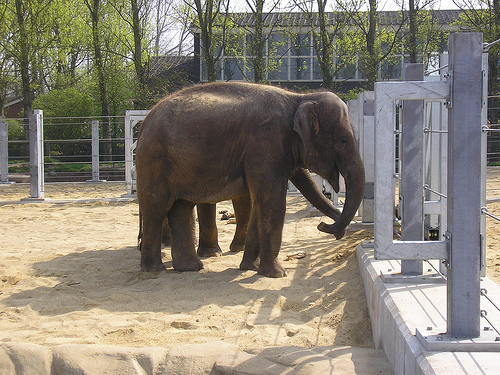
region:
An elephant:
[198, 91, 279, 248]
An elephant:
[208, 74, 400, 366]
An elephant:
[204, 108, 314, 289]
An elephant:
[173, 56, 336, 302]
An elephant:
[185, 48, 302, 214]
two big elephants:
[128, 77, 366, 280]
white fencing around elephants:
[350, 35, 496, 371]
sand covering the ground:
[3, 196, 365, 343]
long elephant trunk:
[316, 155, 371, 234]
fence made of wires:
[6, 118, 123, 180]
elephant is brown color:
[128, 76, 365, 281]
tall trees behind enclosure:
[7, 3, 498, 120]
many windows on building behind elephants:
[191, 12, 448, 75]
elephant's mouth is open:
[326, 155, 352, 196]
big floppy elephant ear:
[290, 95, 323, 170]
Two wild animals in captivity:
[58, 47, 416, 319]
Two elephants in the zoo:
[19, 40, 459, 342]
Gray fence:
[338, 45, 493, 359]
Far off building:
[139, 3, 497, 186]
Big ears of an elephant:
[293, 94, 358, 208]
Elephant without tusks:
[102, 82, 399, 274]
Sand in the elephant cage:
[8, 213, 178, 335]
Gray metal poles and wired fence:
[11, 104, 136, 191]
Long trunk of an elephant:
[306, 91, 372, 245]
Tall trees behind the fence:
[8, 2, 150, 111]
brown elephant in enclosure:
[118, 61, 363, 284]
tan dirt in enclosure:
[23, 285, 348, 346]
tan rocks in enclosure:
[20, 345, 370, 370]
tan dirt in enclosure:
[11, 210, 132, 311]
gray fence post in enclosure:
[19, 107, 55, 199]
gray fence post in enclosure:
[439, 22, 486, 325]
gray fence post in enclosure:
[381, 65, 448, 260]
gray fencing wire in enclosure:
[49, 112, 121, 189]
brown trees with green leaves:
[12, 8, 154, 108]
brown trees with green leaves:
[185, 7, 422, 74]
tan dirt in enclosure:
[37, 283, 207, 341]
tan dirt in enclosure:
[215, 282, 354, 329]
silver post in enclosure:
[25, 110, 55, 192]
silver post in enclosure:
[376, 25, 491, 342]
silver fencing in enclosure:
[49, 109, 121, 192]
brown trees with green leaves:
[364, 8, 485, 27]